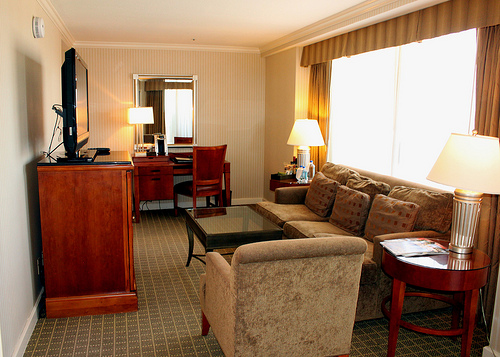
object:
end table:
[375, 235, 497, 355]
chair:
[198, 230, 368, 355]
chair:
[188, 143, 227, 205]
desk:
[131, 150, 237, 212]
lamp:
[286, 118, 328, 183]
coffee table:
[182, 204, 284, 252]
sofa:
[259, 158, 453, 240]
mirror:
[131, 73, 197, 148]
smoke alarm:
[27, 7, 42, 36]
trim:
[183, 208, 269, 270]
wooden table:
[387, 231, 484, 278]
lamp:
[429, 118, 498, 263]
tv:
[59, 48, 91, 159]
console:
[40, 147, 137, 316]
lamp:
[128, 101, 158, 151]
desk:
[128, 132, 230, 217]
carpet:
[25, 216, 490, 353]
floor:
[30, 202, 489, 354]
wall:
[69, 42, 266, 207]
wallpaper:
[233, 52, 256, 186]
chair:
[187, 142, 224, 213]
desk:
[133, 155, 233, 215]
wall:
[260, 0, 499, 316]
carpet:
[153, 201, 298, 332]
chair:
[176, 142, 227, 212]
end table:
[266, 172, 313, 189]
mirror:
[127, 69, 202, 151]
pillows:
[302, 157, 452, 242]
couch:
[253, 159, 464, 324]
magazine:
[379, 231, 446, 262]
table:
[92, 144, 235, 210]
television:
[43, 42, 109, 163]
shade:
[425, 140, 484, 197]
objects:
[253, 148, 314, 198]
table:
[376, 221, 462, 330]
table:
[183, 205, 283, 267]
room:
[2, 0, 497, 352]